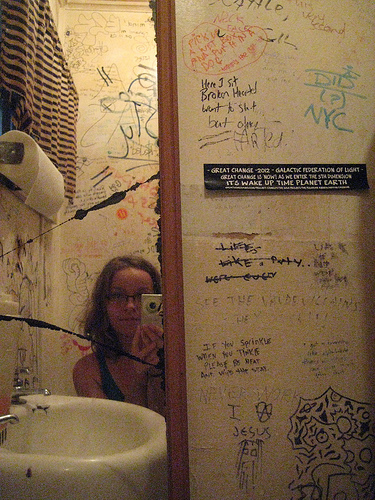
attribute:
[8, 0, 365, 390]
wall — yellow, full of words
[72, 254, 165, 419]
girl — caucasian, brunette, wearing glasses, young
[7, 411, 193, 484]
sink — white, porcelain, chipped, round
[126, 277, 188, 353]
camera — small, silver, digital, round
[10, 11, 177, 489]
mirror — cracked, rectangular, long, clear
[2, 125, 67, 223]
paper towels — white, circular, thin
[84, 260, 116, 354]
hair — medium length, brunette, fine textured, curls at the end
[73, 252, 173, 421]
girl — caucasian, brunette, young, wearing glasses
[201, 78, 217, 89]
word — print, legible, green, black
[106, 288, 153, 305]
glasses — round, black rimmed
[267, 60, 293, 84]
ground — yellow, handwritting, graffiti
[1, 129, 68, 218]
paper towels — white, thin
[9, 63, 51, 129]
curtain — Black , tan , striped 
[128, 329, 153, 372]
hand — young, pink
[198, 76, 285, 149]
words — black, print, legible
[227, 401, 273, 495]
writing — black 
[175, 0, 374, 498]
wall — wordy, yellow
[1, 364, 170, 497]
sink — porcelain, white, chipped, round